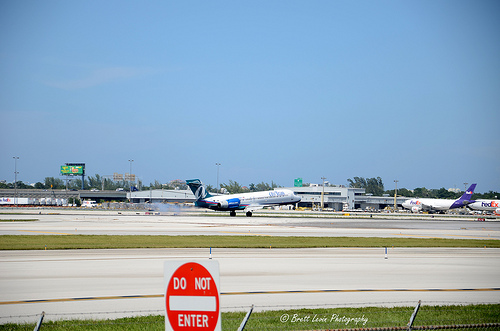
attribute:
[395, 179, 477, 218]
plane — white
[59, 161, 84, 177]
sign — green, rectangle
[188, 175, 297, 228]
plane — white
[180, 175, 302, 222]
plane — white, blue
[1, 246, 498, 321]
run way — concrete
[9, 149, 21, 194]
post — tall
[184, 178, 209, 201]
design — white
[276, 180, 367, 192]
roof — flat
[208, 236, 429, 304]
surface — paved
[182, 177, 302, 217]
plane — landing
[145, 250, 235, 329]
sign — metal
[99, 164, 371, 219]
plane — white, speeding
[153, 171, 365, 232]
plane — blue, white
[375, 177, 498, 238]
plane — blue, white